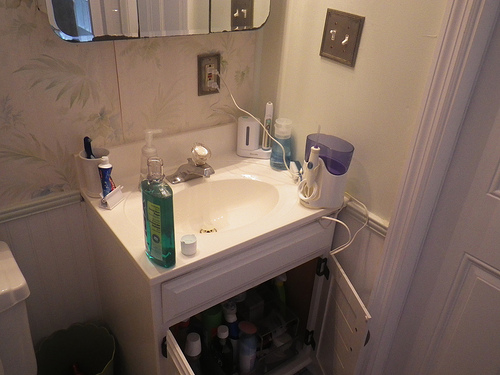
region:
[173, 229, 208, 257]
cap placed on sink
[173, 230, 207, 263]
white cap on sink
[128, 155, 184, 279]
mouthwash at sink area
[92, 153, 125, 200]
tube of toothpaste at sink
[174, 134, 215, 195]
water faucet in view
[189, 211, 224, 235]
drain area in sink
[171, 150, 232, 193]
metal faucet area on sink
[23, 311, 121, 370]
green garbage pail in view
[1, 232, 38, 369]
part of a toilet area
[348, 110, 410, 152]
part of white wall area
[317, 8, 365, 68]
A light switch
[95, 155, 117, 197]
Tube of toothpaste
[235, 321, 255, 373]
Bathroom cleaner in a cabinet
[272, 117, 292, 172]
A bottle of blue liquid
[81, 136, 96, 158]
A brush handle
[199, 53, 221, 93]
An outlet with plugs in it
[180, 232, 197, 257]
A lid for a bottle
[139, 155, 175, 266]
Mouthwash in a bottle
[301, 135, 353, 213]
Some kind of cleaning device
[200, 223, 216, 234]
A drain in a sink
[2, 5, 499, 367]
a bathroom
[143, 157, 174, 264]
mouthwash on the counter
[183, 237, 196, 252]
the cap to the mouthwash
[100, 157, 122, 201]
toothpaste on the counter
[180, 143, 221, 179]
the faucet of the sink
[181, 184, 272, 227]
the sink in the bathroom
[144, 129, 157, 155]
a soap dispenser on the counter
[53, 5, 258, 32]
the mirror above the sink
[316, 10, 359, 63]
the light switch on the wall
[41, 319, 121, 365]
the waste basket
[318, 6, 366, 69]
two light switches, one turned up and one turned down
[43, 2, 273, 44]
mirror showing a reflection of a shower curtain and light switches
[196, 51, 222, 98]
electrical outlet with two cords plugged into it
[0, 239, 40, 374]
edge of a toilet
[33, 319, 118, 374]
waste basket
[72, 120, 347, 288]
a bathroom sink with items on the counter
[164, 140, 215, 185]
faucet of a sink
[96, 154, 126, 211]
a tube of toothpaste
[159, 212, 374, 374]
a cabinet under a bathroom sink, full of toiletries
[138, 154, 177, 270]
a bottle of mouthwash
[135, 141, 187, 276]
a bottle of mouthwash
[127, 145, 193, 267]
the mouthwash is blue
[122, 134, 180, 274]
the mouthwash is a greenish blue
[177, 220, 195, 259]
the cap to the mouthwash bottle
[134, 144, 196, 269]
the mouthwash bottle is open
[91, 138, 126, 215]
this is a tube of toothpaste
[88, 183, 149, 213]
this is a small stand for the toothpaste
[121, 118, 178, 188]
a bottle of hand soap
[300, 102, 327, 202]
this is an electric flosser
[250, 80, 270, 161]
an electric toothbrush without the bristle